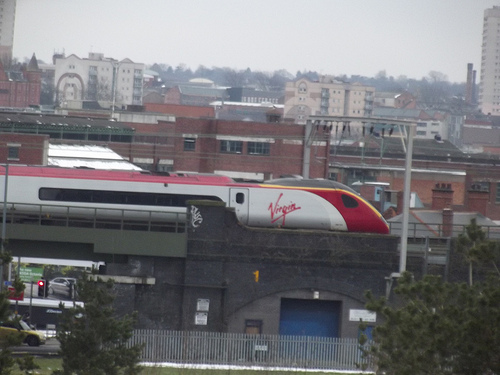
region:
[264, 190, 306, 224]
red logo on the train car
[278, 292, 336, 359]
blue doors to a building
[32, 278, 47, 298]
a traffic signal lit up in red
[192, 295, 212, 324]
two white signs on the concrete wall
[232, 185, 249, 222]
door to the subway train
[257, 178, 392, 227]
yellow stripe on the nose of the subway train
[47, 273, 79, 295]
a silver car on the road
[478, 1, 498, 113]
side of a tall building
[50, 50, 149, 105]
white building with many windows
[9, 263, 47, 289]
green and white street sign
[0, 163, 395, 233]
red and white passenger train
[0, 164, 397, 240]
red and white train going over the bridge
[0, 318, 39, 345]
yellow car going under the bridge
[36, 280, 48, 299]
red stop light at the intersection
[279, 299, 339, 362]
large blue door on the side of the building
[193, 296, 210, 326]
black and white signs on the building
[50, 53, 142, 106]
maroon and white building in the city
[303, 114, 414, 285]
metal scaffolding over the tracks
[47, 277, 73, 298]
silver car parked in the parking lot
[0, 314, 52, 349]
small car driving through the intersection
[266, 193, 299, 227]
The train's brand is Virgin.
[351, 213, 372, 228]
The train is red.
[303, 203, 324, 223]
The train is silver.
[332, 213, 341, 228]
The train is white.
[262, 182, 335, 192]
The train is yellow.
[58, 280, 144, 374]
A tree is below the track.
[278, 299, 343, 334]
A blue door is below the track.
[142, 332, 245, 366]
A fence is below the track.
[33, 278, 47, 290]
The traffic light is red.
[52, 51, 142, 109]
Buildings are in the background.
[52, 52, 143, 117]
White building in background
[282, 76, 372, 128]
Tan building in background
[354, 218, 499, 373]
Large tree in foreground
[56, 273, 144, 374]
Tree behind the fence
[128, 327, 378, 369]
Fence in front of building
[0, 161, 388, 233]
Long white and red train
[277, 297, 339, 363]
Blue doors on building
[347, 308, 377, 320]
White rectangular sign on building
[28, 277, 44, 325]
Traffic light on road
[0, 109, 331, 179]
Large red brick building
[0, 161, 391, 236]
White and red train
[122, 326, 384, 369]
Fence next to sidewalk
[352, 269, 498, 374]
Green tree in foreground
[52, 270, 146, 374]
Green tree in foreground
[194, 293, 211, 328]
White signs on side of building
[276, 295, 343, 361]
Blue doors on side of building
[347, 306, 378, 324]
White sign on side of building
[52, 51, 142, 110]
Large white building in background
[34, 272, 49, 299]
Stop light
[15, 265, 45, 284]
Green street sign